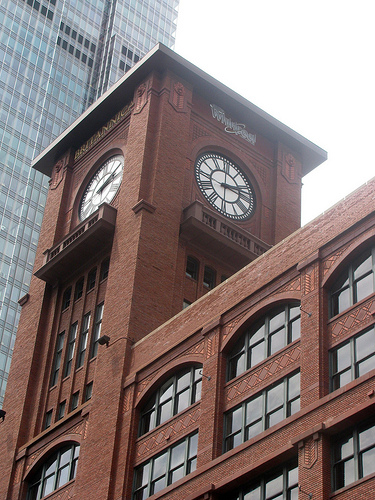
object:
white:
[217, 173, 225, 182]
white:
[100, 179, 105, 184]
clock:
[76, 154, 122, 219]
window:
[123, 359, 202, 495]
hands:
[221, 182, 253, 195]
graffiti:
[208, 105, 258, 145]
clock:
[193, 152, 256, 221]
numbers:
[195, 148, 256, 221]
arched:
[123, 358, 205, 499]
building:
[0, 39, 373, 498]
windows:
[60, 285, 71, 312]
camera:
[96, 334, 109, 346]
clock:
[78, 154, 123, 225]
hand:
[220, 182, 255, 195]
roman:
[195, 152, 253, 215]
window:
[214, 297, 307, 460]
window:
[318, 233, 375, 397]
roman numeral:
[212, 156, 221, 169]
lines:
[270, 380, 299, 420]